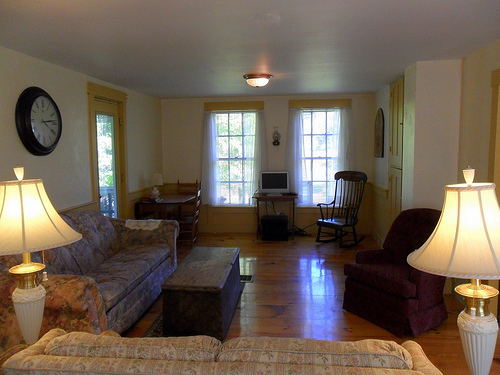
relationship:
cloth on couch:
[120, 211, 164, 237] [28, 160, 194, 331]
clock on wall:
[14, 86, 64, 156] [1, 46, 161, 218]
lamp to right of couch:
[406, 166, 498, 373] [6, 330, 443, 373]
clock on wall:
[14, 86, 66, 156] [0, 44, 157, 235]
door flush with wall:
[365, 68, 417, 238] [21, 64, 441, 227]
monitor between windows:
[255, 165, 290, 195] [208, 102, 354, 210]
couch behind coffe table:
[0, 196, 178, 345] [154, 244, 245, 339]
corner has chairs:
[341, 171, 480, 356] [300, 133, 498, 368]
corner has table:
[341, 171, 480, 356] [132, 168, 212, 247]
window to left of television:
[208, 109, 256, 206] [252, 166, 295, 198]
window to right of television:
[294, 106, 346, 198] [252, 166, 295, 198]